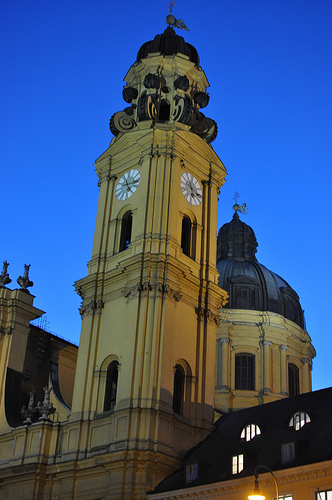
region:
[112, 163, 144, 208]
clock in clock tower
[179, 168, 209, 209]
clock in clock tower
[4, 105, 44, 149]
white clouds in blue sky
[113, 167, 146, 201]
gray and white clock in tower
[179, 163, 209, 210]
gray and white clock in tower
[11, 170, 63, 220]
white clouds in blue sky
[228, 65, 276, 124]
white clouds in blue sky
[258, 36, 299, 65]
white clouds in blue sky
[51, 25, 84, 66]
white clouds in blue sky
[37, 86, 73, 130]
white clouds in blue sky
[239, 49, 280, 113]
white clouds in blue sky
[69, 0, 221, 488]
A clock tower.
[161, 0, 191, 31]
A weather vane on top a clock tower.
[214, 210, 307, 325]
A domed building top.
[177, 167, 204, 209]
A clock on a tower.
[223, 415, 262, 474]
Lit windows in a rooftop.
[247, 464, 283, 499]
A lit street lamp.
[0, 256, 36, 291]
Statues on top a wall.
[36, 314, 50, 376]
A ladder on the side of a wall.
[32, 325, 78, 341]
A fence on top a wall.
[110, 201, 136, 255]
An arched opening in a clock tower.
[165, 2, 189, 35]
a weather vane atop a building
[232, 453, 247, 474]
light filtering through a square window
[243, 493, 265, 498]
a white street light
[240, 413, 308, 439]
two domed white lit windows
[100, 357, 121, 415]
a dark archway on a building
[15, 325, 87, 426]
the area between two spires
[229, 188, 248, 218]
a weather vane on a rotunda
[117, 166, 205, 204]
two clocks on a building tower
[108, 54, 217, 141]
the ornate top of a tower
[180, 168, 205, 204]
Clock on a tower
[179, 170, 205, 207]
White and grey clock on tower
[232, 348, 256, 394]
Window on a building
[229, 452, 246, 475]
The light is on inside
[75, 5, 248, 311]
this build in a treasure that has been around for centuries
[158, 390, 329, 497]
this is a portion of the building that employes people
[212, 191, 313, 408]
this tower like structure has an extensive glass filled top to illuminate the sun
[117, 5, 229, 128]
the top of the highest tower has a direction, weather steel guide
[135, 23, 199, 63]
a domed roof on a tower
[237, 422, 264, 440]
an arched window in a roof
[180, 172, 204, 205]
a clock on the side of a tower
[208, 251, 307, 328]
a domed roof on a round room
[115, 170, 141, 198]
a clock on the side of a tower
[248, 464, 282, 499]
a lighted street light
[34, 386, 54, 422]
a statue on top of a building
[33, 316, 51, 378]
a ladder leading to the roof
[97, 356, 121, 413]
an arched window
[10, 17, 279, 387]
this is a classical building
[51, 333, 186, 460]
the building is stone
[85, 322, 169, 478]
the building is yellow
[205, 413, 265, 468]
the roof is black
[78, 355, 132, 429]
the windows are arched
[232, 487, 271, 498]
the light is yellow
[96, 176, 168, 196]
the clock is gray and white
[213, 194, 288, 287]
the tower is domed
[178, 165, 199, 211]
There is a clock on the large tower.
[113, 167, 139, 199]
There is a clock on the large tower.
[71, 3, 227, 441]
A large tower is part of the big building.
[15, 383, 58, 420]
Ornate decorations are on the front of the building.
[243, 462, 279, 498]
A lamp post is providing light on the front of the building.